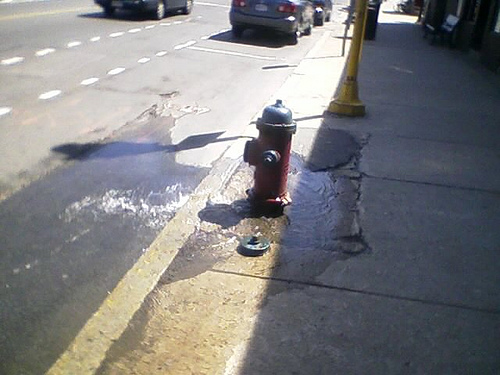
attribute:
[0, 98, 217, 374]
water — flowing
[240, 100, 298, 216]
fire hydrant — red, open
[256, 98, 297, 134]
top — grey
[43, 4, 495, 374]
sidewalk — broken, paved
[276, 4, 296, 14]
light — red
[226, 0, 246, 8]
light — red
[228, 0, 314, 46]
car — parked, grey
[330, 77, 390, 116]
base — yellow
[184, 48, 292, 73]
line — white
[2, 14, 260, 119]
line — white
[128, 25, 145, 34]
line — white